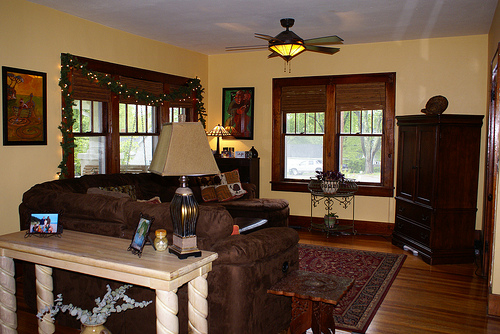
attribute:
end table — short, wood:
[266, 268, 354, 332]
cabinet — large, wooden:
[372, 99, 497, 247]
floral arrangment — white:
[38, 280, 152, 332]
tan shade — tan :
[157, 128, 242, 186]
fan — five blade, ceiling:
[220, 27, 343, 73]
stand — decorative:
[309, 184, 360, 240]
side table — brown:
[246, 267, 333, 324]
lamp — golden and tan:
[149, 108, 219, 258]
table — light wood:
[0, 224, 226, 324]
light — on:
[269, 46, 306, 60]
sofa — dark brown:
[1, 116, 386, 329]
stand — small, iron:
[310, 179, 355, 241]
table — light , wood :
[3, 205, 225, 328]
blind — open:
[332, 79, 387, 109]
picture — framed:
[126, 215, 153, 257]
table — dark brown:
[262, 259, 369, 334]